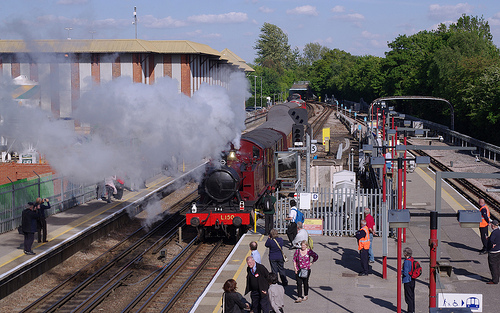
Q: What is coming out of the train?
A: Smoke.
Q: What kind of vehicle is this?
A: Train.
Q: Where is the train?
A: Train tracks.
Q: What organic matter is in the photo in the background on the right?
A: Trees.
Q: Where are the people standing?
A: Train station platform.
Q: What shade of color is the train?
A: Red and black.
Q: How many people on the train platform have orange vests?
A: Two.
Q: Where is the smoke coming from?
A: The train engine's smokestack.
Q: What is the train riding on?
A: Tracks.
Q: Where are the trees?
A: In the background to the right.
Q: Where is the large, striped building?
A: In the background to the left.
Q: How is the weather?
A: It is sunny.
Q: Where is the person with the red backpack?
A: At the lower right between the red poles.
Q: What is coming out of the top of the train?
A: Smoke.